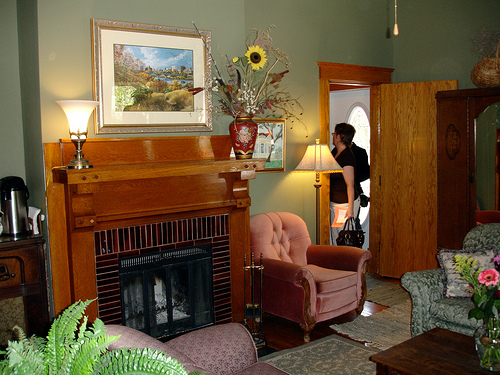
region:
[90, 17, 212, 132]
a fancied framed picture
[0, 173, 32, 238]
a black and metal coffee thermos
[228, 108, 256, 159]
a red and gold decorative vase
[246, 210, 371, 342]
a pink arm chair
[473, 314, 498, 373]
a clear vase on wooden table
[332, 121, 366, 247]
person standing in doorway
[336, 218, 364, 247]
a black leather pocket book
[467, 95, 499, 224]
a mirror on a wooden piece of furniture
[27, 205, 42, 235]
white square napkins in holder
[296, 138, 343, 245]
standing lamp with lit light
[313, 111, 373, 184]
lady in the doorway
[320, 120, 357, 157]
head of the lady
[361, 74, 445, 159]
door next to the lady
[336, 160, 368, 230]
arm of the lady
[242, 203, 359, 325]
couch in the room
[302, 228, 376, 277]
arm of the couch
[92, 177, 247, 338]
fireplace in the room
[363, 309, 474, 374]
table in the room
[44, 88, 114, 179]
light above the fireplace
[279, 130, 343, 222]
lamp in the room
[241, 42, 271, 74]
A yellow sunflower with a dark center.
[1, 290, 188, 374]
A green fern plant with many leaves.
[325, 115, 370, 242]
A woman standing in the doorway.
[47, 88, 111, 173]
A lamp that is turned on.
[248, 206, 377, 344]
A pink colored arm chair.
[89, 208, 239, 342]
A fireplace with brick around it.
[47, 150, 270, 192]
A wooden mantel above the fireplace.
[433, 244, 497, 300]
A pillow sitting on a piece of furniture.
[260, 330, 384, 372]
A white and gray patterned rug.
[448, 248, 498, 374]
A vase of flowers on the coffee table.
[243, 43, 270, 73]
a large yellow sun flower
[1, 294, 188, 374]
a green fern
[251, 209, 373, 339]
a pink chair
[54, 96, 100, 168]
a silver and white lamp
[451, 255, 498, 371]
a vase of flowers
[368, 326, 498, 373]
a brown wooden table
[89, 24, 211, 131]
a picture hanging on the wall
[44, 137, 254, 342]
a fire place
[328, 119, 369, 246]
a woman standing in the doorway holding a purse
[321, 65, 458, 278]
an open wooden door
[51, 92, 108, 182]
The lamp is on.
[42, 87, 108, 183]
The lamp is on the mantle.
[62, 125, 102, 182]
The lamp base is brass.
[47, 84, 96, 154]
The lamp shade is white.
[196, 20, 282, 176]
The vase of flowers is on the mantle.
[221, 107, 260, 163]
The vase is red.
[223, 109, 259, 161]
The vase is ceramic.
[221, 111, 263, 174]
The vase is breakable.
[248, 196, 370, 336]
The chair is pink.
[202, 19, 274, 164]
The vase has a sunflower in it.